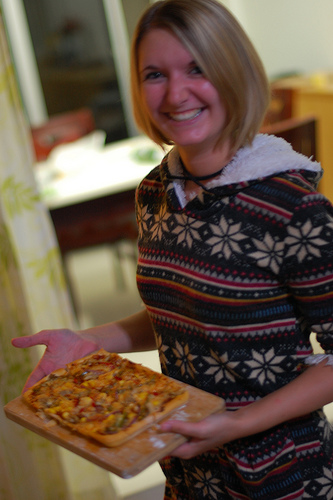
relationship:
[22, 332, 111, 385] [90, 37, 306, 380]
hand of woman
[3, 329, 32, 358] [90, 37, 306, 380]
thumb of woman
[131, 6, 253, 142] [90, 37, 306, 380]
head of woman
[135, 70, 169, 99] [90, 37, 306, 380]
eye of woman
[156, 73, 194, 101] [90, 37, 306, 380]
nose of woman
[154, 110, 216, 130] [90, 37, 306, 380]
mouth of woman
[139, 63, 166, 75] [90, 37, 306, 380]
eyebrow of woman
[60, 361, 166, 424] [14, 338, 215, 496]
pizza on tray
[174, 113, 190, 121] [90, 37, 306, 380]
teeth of woman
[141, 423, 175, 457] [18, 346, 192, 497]
floor on board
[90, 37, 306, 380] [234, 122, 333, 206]
woman has hood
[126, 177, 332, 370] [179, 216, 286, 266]
dress has pattern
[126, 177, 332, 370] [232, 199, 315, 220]
dress has stripe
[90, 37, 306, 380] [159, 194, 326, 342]
woman wearing sweater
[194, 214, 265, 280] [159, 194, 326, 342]
snowflake on sweater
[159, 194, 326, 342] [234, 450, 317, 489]
sweater has pockets